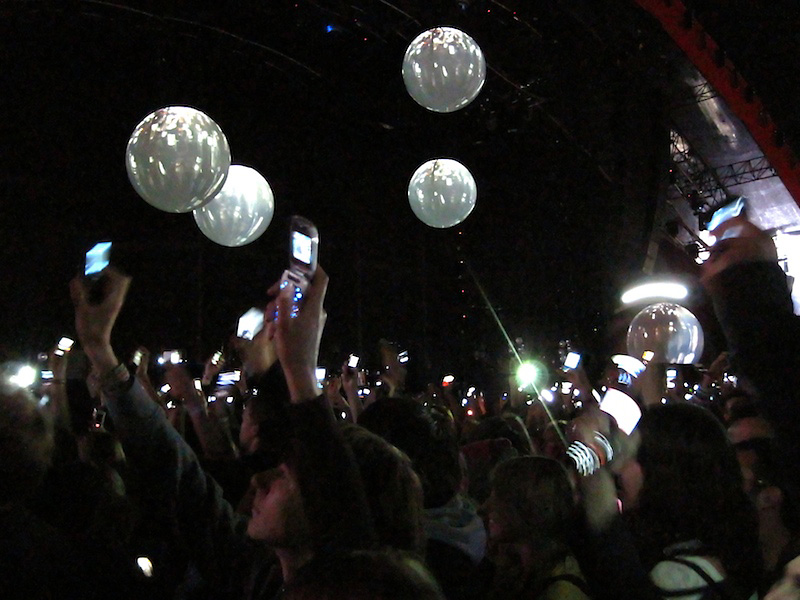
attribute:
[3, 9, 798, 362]
sky — dark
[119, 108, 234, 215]
ball — white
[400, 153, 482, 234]
ball — white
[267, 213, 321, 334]
cell phone — silver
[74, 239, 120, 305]
cell phone — black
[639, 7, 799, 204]
object — red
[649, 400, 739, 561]
hair — black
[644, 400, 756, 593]
hair — long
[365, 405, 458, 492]
hair — dark, short